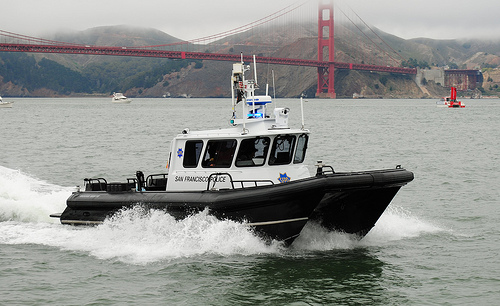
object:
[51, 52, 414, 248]
boat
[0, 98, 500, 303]
water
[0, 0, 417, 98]
bridge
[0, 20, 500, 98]
mountain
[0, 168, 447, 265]
wave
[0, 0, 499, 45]
fog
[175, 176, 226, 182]
letters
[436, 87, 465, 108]
boat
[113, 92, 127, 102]
boat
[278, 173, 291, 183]
star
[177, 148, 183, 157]
star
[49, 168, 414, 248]
bottom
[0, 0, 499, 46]
sky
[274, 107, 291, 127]
camera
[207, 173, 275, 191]
railing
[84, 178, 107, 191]
railing